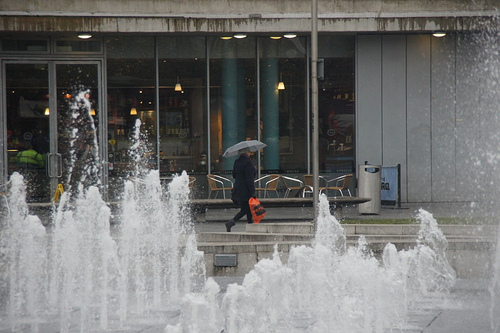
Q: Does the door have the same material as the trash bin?
A: No, the door is made of glass and the trash bin is made of metal.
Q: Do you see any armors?
A: No, there are no armors.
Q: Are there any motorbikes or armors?
A: No, there are no armors or motorbikes.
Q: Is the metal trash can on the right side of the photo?
A: Yes, the garbage bin is on the right of the image.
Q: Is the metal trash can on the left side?
A: No, the garbage bin is on the right of the image.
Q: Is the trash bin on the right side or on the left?
A: The trash bin is on the right of the image.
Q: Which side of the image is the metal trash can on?
A: The trash can is on the right of the image.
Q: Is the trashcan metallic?
A: Yes, the trashcan is metallic.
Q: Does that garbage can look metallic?
A: Yes, the garbage can is metallic.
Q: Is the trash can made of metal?
A: Yes, the trash can is made of metal.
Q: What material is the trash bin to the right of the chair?
A: The trashcan is made of metal.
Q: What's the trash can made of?
A: The trashcan is made of metal.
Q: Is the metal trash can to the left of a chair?
A: No, the garbage can is to the right of a chair.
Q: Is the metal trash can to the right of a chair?
A: Yes, the trashcan is to the right of a chair.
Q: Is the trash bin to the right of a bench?
A: No, the trash bin is to the right of a chair.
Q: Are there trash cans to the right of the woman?
A: Yes, there is a trash can to the right of the woman.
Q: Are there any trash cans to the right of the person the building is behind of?
A: Yes, there is a trash can to the right of the woman.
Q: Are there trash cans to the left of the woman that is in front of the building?
A: No, the trash can is to the right of the woman.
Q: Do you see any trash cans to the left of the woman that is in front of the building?
A: No, the trash can is to the right of the woman.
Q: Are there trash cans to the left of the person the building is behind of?
A: No, the trash can is to the right of the woman.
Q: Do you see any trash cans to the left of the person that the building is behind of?
A: No, the trash can is to the right of the woman.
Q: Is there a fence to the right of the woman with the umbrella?
A: No, there is a trash can to the right of the woman.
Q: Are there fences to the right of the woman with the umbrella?
A: No, there is a trash can to the right of the woman.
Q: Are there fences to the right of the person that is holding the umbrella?
A: No, there is a trash can to the right of the woman.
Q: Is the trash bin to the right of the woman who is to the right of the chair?
A: Yes, the trash bin is to the right of the woman.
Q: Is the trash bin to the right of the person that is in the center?
A: Yes, the trash bin is to the right of the woman.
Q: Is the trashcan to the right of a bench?
A: No, the trashcan is to the right of the woman.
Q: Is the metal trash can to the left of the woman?
A: No, the trash can is to the right of the woman.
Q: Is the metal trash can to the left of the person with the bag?
A: No, the trash can is to the right of the woman.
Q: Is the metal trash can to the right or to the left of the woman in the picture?
A: The trash can is to the right of the woman.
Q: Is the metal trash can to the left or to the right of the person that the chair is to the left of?
A: The trash can is to the right of the woman.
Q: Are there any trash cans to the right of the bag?
A: Yes, there is a trash can to the right of the bag.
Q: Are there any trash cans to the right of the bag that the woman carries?
A: Yes, there is a trash can to the right of the bag.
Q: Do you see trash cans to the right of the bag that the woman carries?
A: Yes, there is a trash can to the right of the bag.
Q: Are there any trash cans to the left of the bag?
A: No, the trash can is to the right of the bag.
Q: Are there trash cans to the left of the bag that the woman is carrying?
A: No, the trash can is to the right of the bag.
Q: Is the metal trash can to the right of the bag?
A: Yes, the trash bin is to the right of the bag.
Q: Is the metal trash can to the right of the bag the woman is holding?
A: Yes, the trash bin is to the right of the bag.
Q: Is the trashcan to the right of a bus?
A: No, the trashcan is to the right of the bag.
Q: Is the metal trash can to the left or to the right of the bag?
A: The trash can is to the right of the bag.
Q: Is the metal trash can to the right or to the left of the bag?
A: The trash can is to the right of the bag.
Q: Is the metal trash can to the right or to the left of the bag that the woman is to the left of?
A: The trash can is to the right of the bag.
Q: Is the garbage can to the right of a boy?
A: No, the garbage can is to the right of a chair.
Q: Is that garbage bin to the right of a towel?
A: No, the garbage bin is to the right of a chair.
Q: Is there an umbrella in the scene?
A: Yes, there is an umbrella.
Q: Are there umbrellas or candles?
A: Yes, there is an umbrella.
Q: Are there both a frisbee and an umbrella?
A: No, there is an umbrella but no frisbees.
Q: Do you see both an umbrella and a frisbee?
A: No, there is an umbrella but no frisbees.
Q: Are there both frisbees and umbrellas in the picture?
A: No, there is an umbrella but no frisbees.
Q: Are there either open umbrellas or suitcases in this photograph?
A: Yes, there is an open umbrella.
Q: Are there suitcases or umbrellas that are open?
A: Yes, the umbrella is open.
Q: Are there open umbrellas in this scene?
A: Yes, there is an open umbrella.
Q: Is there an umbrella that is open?
A: Yes, there is an umbrella that is open.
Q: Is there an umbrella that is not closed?
A: Yes, there is a open umbrella.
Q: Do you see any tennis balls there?
A: No, there are no tennis balls.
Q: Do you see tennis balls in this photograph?
A: No, there are no tennis balls.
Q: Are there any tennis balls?
A: No, there are no tennis balls.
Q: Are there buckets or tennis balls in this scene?
A: No, there are no tennis balls or buckets.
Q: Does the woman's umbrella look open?
A: Yes, the umbrella is open.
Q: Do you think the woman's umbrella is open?
A: Yes, the umbrella is open.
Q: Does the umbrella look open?
A: Yes, the umbrella is open.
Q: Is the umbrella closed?
A: No, the umbrella is open.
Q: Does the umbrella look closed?
A: No, the umbrella is open.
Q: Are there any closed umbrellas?
A: No, there is an umbrella but it is open.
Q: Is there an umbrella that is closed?
A: No, there is an umbrella but it is open.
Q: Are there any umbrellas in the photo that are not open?
A: No, there is an umbrella but it is open.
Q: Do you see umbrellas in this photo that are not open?
A: No, there is an umbrella but it is open.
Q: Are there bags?
A: Yes, there is a bag.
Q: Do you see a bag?
A: Yes, there is a bag.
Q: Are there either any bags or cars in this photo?
A: Yes, there is a bag.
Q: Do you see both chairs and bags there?
A: Yes, there are both a bag and a chair.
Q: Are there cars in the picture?
A: No, there are no cars.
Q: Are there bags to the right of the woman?
A: Yes, there is a bag to the right of the woman.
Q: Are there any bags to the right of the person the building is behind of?
A: Yes, there is a bag to the right of the woman.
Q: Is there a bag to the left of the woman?
A: No, the bag is to the right of the woman.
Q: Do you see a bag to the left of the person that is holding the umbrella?
A: No, the bag is to the right of the woman.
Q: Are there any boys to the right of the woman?
A: No, there is a bag to the right of the woman.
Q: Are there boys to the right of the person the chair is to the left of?
A: No, there is a bag to the right of the woman.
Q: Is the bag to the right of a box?
A: No, the bag is to the right of the woman.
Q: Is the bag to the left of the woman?
A: No, the bag is to the right of the woman.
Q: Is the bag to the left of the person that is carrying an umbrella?
A: No, the bag is to the right of the woman.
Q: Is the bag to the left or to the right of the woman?
A: The bag is to the right of the woman.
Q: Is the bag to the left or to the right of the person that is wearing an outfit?
A: The bag is to the right of the woman.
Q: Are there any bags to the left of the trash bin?
A: Yes, there is a bag to the left of the trash bin.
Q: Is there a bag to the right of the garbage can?
A: No, the bag is to the left of the garbage can.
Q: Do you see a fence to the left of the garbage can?
A: No, there is a bag to the left of the garbage can.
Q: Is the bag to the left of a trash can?
A: Yes, the bag is to the left of a trash can.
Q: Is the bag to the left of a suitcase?
A: No, the bag is to the left of a trash can.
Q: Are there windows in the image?
A: Yes, there is a window.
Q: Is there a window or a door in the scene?
A: Yes, there is a window.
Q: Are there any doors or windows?
A: Yes, there is a window.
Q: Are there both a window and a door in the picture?
A: Yes, there are both a window and a door.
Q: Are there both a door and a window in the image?
A: Yes, there are both a window and a door.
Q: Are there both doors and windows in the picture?
A: Yes, there are both a window and a door.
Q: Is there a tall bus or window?
A: Yes, there is a tall window.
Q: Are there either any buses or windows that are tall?
A: Yes, the window is tall.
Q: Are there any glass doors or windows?
A: Yes, there is a glass window.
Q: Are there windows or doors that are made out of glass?
A: Yes, the window is made of glass.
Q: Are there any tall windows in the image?
A: Yes, there is a tall window.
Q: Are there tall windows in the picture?
A: Yes, there is a tall window.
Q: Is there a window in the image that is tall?
A: Yes, there is a window that is tall.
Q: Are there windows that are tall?
A: Yes, there is a window that is tall.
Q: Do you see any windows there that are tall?
A: Yes, there is a window that is tall.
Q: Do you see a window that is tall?
A: Yes, there is a window that is tall.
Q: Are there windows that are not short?
A: Yes, there is a tall window.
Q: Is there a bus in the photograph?
A: No, there are no buses.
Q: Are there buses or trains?
A: No, there are no buses or trains.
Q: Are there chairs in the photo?
A: Yes, there is a chair.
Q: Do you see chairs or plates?
A: Yes, there is a chair.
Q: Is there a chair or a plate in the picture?
A: Yes, there is a chair.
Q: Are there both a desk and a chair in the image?
A: No, there is a chair but no desks.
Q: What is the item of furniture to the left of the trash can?
A: The piece of furniture is a chair.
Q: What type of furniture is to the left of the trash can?
A: The piece of furniture is a chair.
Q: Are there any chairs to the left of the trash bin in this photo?
A: Yes, there is a chair to the left of the trash bin.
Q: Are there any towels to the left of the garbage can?
A: No, there is a chair to the left of the garbage can.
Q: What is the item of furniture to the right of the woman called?
A: The piece of furniture is a chair.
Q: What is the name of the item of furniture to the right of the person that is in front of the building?
A: The piece of furniture is a chair.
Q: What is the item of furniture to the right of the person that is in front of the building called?
A: The piece of furniture is a chair.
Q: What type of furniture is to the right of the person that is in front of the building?
A: The piece of furniture is a chair.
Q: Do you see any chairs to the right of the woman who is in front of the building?
A: Yes, there is a chair to the right of the woman.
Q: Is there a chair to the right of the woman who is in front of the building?
A: Yes, there is a chair to the right of the woman.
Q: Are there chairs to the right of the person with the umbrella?
A: Yes, there is a chair to the right of the woman.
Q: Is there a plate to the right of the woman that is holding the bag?
A: No, there is a chair to the right of the woman.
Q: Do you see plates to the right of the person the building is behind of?
A: No, there is a chair to the right of the woman.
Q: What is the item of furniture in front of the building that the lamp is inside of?
A: The piece of furniture is a chair.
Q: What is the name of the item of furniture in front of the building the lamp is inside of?
A: The piece of furniture is a chair.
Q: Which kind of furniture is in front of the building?
A: The piece of furniture is a chair.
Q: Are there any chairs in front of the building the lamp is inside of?
A: Yes, there is a chair in front of the building.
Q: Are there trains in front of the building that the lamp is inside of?
A: No, there is a chair in front of the building.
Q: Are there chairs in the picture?
A: Yes, there is a chair.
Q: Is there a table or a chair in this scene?
A: Yes, there is a chair.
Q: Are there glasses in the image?
A: No, there are no glasses.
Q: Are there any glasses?
A: No, there are no glasses.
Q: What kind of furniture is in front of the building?
A: The piece of furniture is a chair.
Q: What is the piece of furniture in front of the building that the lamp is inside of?
A: The piece of furniture is a chair.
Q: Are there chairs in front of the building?
A: Yes, there is a chair in front of the building.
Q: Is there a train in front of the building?
A: No, there is a chair in front of the building.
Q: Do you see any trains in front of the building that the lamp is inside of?
A: No, there is a chair in front of the building.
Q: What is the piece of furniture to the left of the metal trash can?
A: The piece of furniture is a chair.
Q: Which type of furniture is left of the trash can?
A: The piece of furniture is a chair.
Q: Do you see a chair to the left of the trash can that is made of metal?
A: Yes, there is a chair to the left of the trash can.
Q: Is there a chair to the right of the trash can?
A: No, the chair is to the left of the trash can.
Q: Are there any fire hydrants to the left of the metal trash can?
A: No, there is a chair to the left of the garbage can.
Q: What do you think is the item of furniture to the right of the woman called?
A: The piece of furniture is a chair.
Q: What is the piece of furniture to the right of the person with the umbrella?
A: The piece of furniture is a chair.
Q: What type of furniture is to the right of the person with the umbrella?
A: The piece of furniture is a chair.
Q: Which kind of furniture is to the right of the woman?
A: The piece of furniture is a chair.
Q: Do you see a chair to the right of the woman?
A: Yes, there is a chair to the right of the woman.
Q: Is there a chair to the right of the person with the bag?
A: Yes, there is a chair to the right of the woman.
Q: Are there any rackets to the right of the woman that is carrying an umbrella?
A: No, there is a chair to the right of the woman.